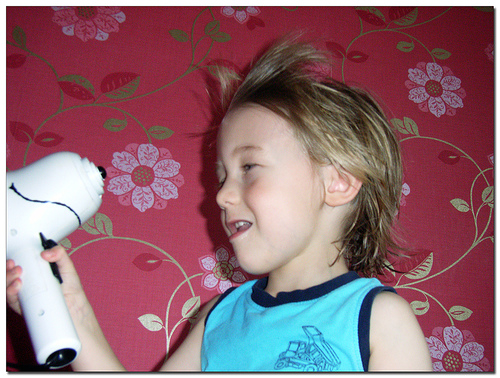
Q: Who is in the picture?
A: A young child.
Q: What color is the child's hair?
A: Blonde.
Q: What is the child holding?
A: Hair dryer.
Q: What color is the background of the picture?
A: Red.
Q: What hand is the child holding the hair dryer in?
A: Right hand.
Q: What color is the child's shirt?
A: Blue.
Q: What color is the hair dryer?
A: White and black.